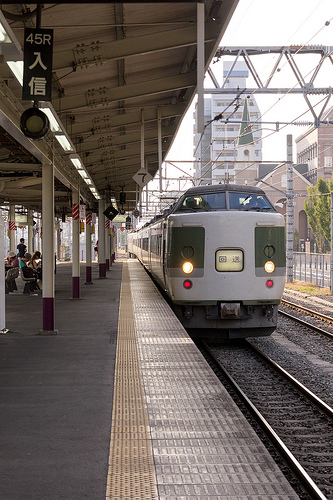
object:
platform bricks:
[104, 256, 298, 499]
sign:
[131, 168, 153, 187]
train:
[128, 185, 288, 342]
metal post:
[98, 199, 106, 278]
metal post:
[39, 154, 59, 338]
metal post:
[71, 182, 80, 300]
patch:
[72, 202, 80, 220]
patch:
[85, 212, 92, 225]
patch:
[105, 219, 110, 229]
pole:
[85, 210, 93, 284]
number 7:
[137, 172, 147, 182]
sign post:
[132, 108, 154, 189]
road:
[205, 331, 333, 499]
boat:
[137, 179, 290, 333]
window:
[178, 190, 274, 212]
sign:
[22, 28, 54, 102]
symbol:
[29, 52, 46, 70]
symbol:
[27, 76, 46, 95]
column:
[39, 152, 59, 336]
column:
[69, 192, 82, 299]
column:
[84, 211, 93, 285]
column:
[98, 200, 106, 277]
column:
[105, 215, 110, 271]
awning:
[3, 0, 240, 213]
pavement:
[0, 250, 300, 499]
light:
[181, 243, 277, 291]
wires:
[144, 49, 328, 182]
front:
[169, 183, 286, 341]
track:
[171, 301, 332, 500]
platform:
[0, 257, 299, 499]